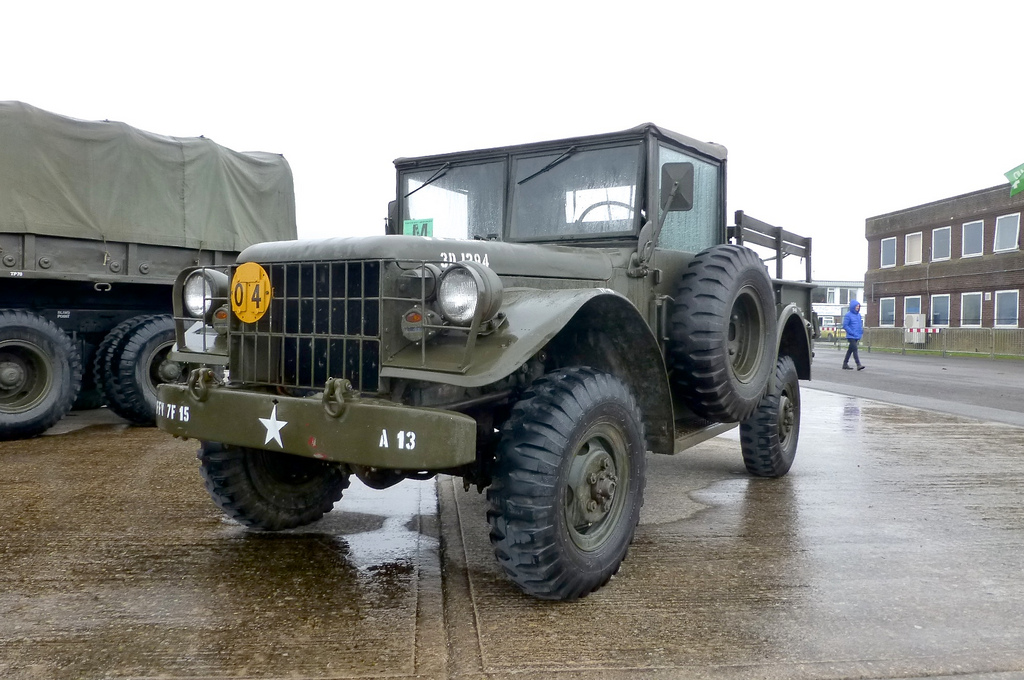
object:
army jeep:
[150, 121, 818, 602]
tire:
[670, 242, 779, 424]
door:
[655, 243, 783, 427]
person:
[841, 298, 868, 371]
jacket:
[841, 300, 863, 340]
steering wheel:
[573, 200, 644, 223]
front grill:
[153, 235, 481, 470]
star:
[257, 403, 292, 448]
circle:
[230, 260, 273, 323]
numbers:
[395, 430, 415, 450]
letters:
[378, 429, 389, 448]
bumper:
[154, 383, 475, 472]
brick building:
[863, 182, 1024, 356]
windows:
[881, 211, 1020, 269]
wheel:
[197, 422, 351, 532]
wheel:
[480, 363, 649, 603]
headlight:
[180, 267, 216, 321]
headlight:
[433, 262, 480, 327]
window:
[931, 226, 951, 263]